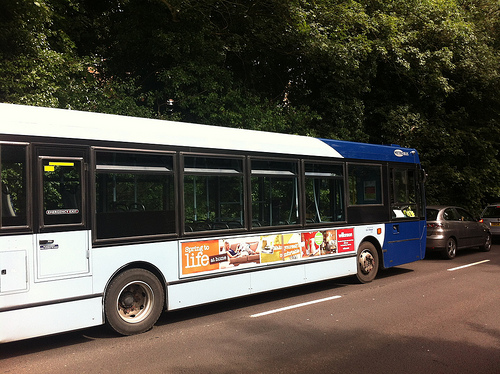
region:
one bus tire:
[108, 266, 164, 329]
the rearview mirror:
[416, 165, 426, 184]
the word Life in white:
[183, 250, 207, 268]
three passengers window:
[98, 156, 301, 237]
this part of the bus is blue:
[386, 220, 424, 264]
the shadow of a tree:
[258, 323, 498, 371]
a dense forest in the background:
[86, 23, 418, 83]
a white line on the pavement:
[246, 295, 343, 316]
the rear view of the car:
[425, 206, 445, 253]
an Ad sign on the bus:
[177, 230, 350, 271]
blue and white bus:
[67, 108, 423, 301]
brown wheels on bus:
[342, 238, 382, 301]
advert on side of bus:
[174, 221, 355, 280]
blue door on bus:
[379, 159, 443, 265]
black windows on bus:
[96, 152, 409, 235]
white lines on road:
[261, 249, 483, 323]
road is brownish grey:
[260, 280, 480, 357]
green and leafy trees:
[4, 20, 479, 177]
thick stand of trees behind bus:
[28, 19, 498, 156]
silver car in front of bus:
[418, 195, 498, 253]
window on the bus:
[113, 166, 160, 234]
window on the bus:
[27, 154, 81, 227]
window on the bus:
[0, 150, 25, 224]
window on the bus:
[182, 163, 236, 235]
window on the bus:
[259, 173, 300, 231]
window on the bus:
[310, 175, 330, 216]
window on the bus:
[341, 165, 371, 207]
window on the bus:
[389, 171, 416, 211]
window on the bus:
[187, 169, 239, 231]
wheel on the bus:
[113, 273, 165, 338]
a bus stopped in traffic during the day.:
[2, 100, 427, 336]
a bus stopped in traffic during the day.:
[0, 100, 422, 334]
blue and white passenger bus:
[1, 100, 430, 344]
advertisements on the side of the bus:
[175, 225, 357, 279]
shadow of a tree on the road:
[178, 316, 498, 371]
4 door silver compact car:
[424, 203, 491, 260]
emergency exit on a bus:
[28, 141, 93, 283]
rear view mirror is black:
[419, 165, 428, 184]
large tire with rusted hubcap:
[103, 265, 167, 334]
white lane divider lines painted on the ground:
[246, 255, 490, 321]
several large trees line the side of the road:
[0, 0, 499, 206]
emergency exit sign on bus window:
[44, 206, 79, 216]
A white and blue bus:
[0, 95, 435, 353]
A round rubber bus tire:
[96, 257, 171, 342]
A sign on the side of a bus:
[175, 215, 360, 280]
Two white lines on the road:
[241, 250, 491, 321]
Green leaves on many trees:
[0, 0, 495, 220]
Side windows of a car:
[438, 197, 484, 229]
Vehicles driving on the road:
[0, 95, 495, 370]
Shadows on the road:
[161, 299, 499, 371]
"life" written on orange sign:
[180, 242, 216, 272]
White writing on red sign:
[330, 215, 360, 258]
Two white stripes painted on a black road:
[247, 254, 490, 319]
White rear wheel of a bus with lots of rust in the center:
[114, 279, 154, 324]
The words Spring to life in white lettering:
[185, 243, 210, 270]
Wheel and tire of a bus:
[355, 241, 380, 283]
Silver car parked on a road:
[423, 203, 493, 260]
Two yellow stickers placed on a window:
[40, 160, 72, 172]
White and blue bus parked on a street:
[1, 101, 429, 346]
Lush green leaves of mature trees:
[0, 0, 499, 220]